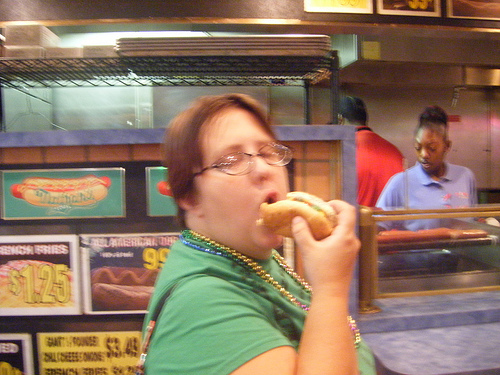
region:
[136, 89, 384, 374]
a person eating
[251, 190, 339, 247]
a hotdog a person is eating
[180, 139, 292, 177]
eyeglasses the person is wearing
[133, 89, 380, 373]
a person wearing green shirt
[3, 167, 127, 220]
a hot dog sign on the wall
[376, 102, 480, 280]
a black lady in blue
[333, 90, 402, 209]
a back of a person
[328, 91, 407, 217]
a person in red shirt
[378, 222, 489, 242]
hot dogs on display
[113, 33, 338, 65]
stack of cookie sheets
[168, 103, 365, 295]
person eating hot dog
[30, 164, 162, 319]
signs of food and words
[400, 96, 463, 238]
woman serving food at a restaurant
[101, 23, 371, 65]
metal trays in a restaurant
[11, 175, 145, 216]
sign with a hot dog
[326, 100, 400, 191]
man in a red shirt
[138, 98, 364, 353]
person in a green shirt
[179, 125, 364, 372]
person wearing multi colored beads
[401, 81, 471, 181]
woman with her hair up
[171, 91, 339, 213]
person wearing glasses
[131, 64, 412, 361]
a person eating a hotdog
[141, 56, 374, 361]
a person holding a hotdog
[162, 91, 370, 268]
a hotdog in a person's mouth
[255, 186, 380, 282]
a hotdog in a hand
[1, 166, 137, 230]
a decorative hotdog sign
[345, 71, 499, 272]
a girl working with food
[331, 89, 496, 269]
two restaurant employees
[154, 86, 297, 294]
a person wearing glasses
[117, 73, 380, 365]
a person wearing several necklaces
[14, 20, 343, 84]
trays on a shelf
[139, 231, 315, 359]
woman wearing a green shirt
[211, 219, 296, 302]
multiple metallic beads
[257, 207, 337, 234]
a half eaten hot dog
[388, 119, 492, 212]
a woman looking down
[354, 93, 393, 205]
a cook wearing a red shirt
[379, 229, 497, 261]
rows of hot dogs on grills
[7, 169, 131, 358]
multiple colored hot dog signs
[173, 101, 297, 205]
woman with short hair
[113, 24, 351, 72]
silver long baking trays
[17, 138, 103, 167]
blue counter with red brick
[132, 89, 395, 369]
person with glasses eating hot dog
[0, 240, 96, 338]
ad for french fries costing about one dollar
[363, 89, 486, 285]
cafeteria worker in blue polo shirt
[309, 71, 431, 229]
chef in red shirt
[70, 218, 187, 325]
ad for hot dog costing about one dollar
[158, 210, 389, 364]
Mardi Gras beads in various colors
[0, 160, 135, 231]
ad for hot dog on green background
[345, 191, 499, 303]
wood and glass partition at cafeteria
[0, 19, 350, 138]
wire mesh shelving unit with trays atop it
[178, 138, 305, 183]
eye glasses